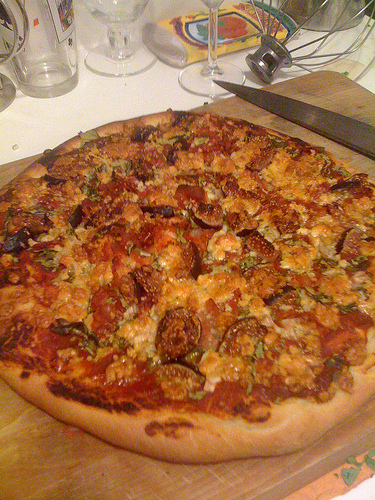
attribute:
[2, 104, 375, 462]
pizza — baked, hot, homemade, fresh, well-done, big, whole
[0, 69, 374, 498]
board — cutting, wooden, surface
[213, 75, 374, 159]
knife — blade, large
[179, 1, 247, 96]
glass — wine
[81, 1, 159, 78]
glass — clear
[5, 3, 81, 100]
glass — pint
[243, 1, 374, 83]
whisk — metal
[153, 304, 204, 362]
topping — pepperoni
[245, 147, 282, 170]
topping — mushroom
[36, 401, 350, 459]
crust — thick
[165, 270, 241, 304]
cheese — melted, yellow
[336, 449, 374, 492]
leaf — oregano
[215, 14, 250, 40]
picture — tomato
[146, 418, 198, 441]
spot — brown